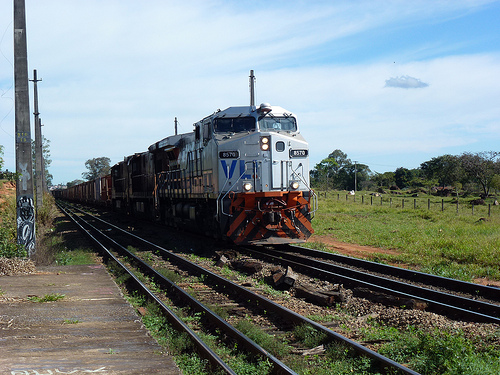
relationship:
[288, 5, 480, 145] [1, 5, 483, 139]
cloud in sky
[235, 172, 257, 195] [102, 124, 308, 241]
lights on front of train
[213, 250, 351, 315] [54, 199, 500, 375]
wood on track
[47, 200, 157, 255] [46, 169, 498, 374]
shadow cast on ground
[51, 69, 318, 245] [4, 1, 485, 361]
car passing through rural area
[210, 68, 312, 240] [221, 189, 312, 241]
front end with stripes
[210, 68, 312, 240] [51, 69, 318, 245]
front end of car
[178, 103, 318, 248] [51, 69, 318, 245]
caboose of car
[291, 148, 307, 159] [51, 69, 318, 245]
number on car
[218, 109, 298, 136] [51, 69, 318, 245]
window on car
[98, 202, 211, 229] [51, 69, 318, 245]
bottom of car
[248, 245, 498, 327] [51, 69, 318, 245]
track under car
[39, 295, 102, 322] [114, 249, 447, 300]
cement next to tracks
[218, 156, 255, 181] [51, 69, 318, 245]
writing on car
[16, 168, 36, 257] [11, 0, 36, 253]
graffitti painted  on pole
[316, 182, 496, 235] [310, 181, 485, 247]
fencing in field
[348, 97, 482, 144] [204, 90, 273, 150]
cloud in sky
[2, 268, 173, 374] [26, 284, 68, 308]
platform with weeds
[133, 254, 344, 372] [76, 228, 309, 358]
lines of track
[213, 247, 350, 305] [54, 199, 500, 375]
wood in between track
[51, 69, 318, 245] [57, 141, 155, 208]
car pulling car